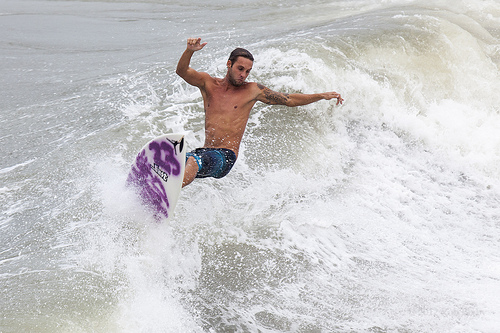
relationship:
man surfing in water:
[162, 33, 346, 190] [1, 2, 500, 332]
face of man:
[237, 63, 252, 84] [162, 33, 346, 190]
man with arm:
[162, 33, 346, 190] [260, 80, 347, 111]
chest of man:
[201, 84, 245, 148] [162, 33, 346, 190]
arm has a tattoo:
[260, 80, 347, 111] [256, 83, 289, 106]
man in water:
[162, 33, 346, 190] [1, 2, 500, 332]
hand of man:
[184, 35, 207, 54] [162, 33, 346, 190]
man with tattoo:
[162, 33, 346, 190] [256, 83, 289, 106]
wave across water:
[103, 46, 500, 331] [1, 2, 500, 332]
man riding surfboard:
[162, 33, 346, 190] [125, 130, 188, 222]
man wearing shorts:
[162, 33, 346, 190] [183, 142, 240, 182]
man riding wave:
[162, 33, 346, 190] [103, 46, 500, 331]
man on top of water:
[162, 33, 346, 190] [1, 2, 500, 332]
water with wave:
[1, 2, 500, 332] [103, 46, 500, 331]